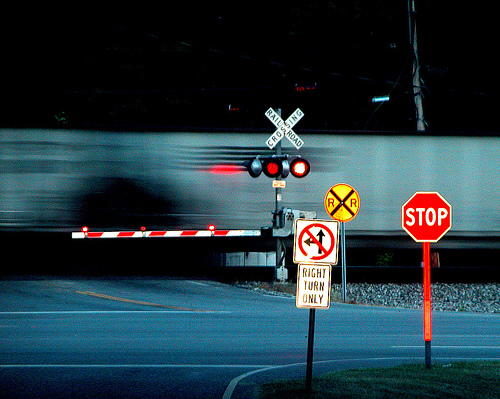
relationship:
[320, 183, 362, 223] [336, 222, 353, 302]
sign on pole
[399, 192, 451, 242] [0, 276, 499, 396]
sign beside paved road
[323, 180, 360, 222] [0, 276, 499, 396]
sign beside paved road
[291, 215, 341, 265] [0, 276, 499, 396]
sign beside paved road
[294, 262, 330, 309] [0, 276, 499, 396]
sign beside paved road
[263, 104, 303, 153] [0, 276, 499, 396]
sign beside paved road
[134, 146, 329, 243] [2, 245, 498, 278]
train running on railroad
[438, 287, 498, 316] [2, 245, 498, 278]
gray rocks beside railroad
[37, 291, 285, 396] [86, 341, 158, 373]
paved road with white lines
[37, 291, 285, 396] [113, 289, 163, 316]
paved road with yellow lines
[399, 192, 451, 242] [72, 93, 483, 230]
sign in front of a train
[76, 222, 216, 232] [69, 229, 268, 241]
lights on a guard rail